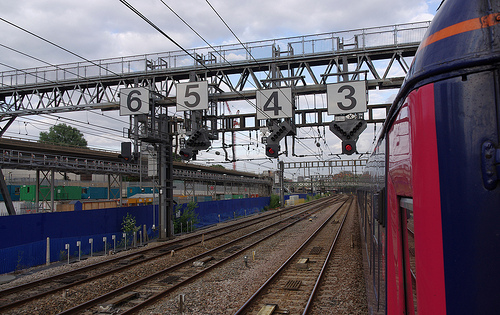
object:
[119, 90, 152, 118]
number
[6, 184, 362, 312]
track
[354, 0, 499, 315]
train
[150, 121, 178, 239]
pole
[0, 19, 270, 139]
power lines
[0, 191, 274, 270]
fence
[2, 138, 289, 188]
bridge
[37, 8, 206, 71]
clouds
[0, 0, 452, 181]
sky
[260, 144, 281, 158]
lights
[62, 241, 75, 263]
pole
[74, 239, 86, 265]
pole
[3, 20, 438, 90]
rails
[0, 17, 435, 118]
walkway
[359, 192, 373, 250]
window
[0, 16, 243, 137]
wires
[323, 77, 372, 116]
sign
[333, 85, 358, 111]
three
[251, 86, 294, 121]
sign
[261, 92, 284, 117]
four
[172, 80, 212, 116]
sign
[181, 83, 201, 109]
five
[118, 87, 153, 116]
sign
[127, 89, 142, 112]
six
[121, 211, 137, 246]
plant